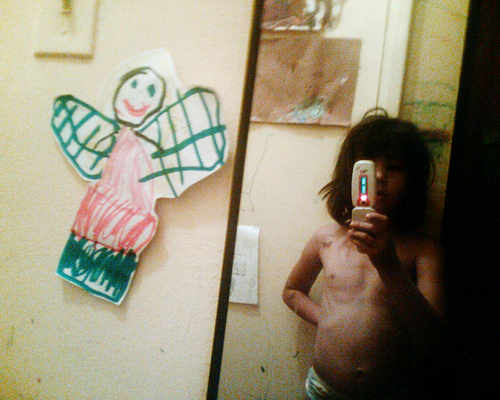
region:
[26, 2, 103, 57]
White light switch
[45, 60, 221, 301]
A paper drawing of an angel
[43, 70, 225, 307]
Green and pink color on angel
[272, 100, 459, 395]
Child leaning against wall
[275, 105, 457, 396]
Child with dark brown hair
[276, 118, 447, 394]
Child looking at a cell phone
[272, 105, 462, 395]
Child with no shirt on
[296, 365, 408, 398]
Child in just underwear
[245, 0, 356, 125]
Paper drawings hanging on wall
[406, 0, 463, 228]
Peach and green color on wall behind child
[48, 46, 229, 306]
child's artwork of an angel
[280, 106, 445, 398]
child using cell phone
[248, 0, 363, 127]
two pieces of a child's artwork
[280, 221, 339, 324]
arm being held behind child's back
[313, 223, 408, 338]
child's bare chest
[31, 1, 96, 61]
electrical light switch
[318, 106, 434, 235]
shoulder length dark brown hair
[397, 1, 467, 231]
yellow curtain with green stripes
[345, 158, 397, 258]
hand holding an open cell phone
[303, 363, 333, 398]
turquoise printed underwear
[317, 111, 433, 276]
child holding a cell phone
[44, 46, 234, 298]
a child's drawing on a wall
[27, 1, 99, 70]
partial part of a light switch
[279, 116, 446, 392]
a child holding a cell phone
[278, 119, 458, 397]
a child with no shirt on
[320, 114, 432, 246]
a child with unkempt hair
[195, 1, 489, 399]
a child taking a picture in front of mirror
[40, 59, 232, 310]
child's drawing of an angel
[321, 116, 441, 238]
a child with brown hair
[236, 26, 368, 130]
a child's drawing hung on a wall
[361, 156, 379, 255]
Child is holding a phone.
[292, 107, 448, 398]
Child is taking a selfie.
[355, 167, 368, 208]
Blue light on the phone.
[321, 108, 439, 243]
The child has brown hair.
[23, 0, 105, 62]
The light switch is on.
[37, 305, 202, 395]
The wall is off white.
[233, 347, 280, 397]
Marks on the wall.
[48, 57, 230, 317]
Drawing on a paper.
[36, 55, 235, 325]
The paper is on the wall.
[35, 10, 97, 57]
The light switch is white.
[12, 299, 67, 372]
a white wall.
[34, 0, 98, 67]
a white light switch.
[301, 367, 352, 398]
a baby is wearing under ware.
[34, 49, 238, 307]
a paper drawing is on the wall.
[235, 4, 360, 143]
a kids paint drawings.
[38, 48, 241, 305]
a kids drawing of a person.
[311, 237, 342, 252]
a boy has a butterfly tattoo.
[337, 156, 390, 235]
a boy is holding a cell phone.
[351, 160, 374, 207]
a cell phone with lights.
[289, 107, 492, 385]
a kid is using a white cell phone.